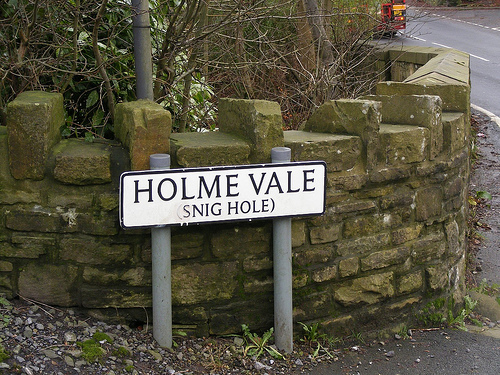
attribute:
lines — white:
[418, 24, 499, 81]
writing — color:
[132, 166, 317, 226]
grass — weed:
[449, 292, 479, 327]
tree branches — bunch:
[152, 0, 402, 132]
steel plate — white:
[120, 152, 330, 231]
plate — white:
[122, 150, 324, 214]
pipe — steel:
[126, 15, 159, 94]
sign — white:
[116, 160, 331, 228]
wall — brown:
[0, 38, 472, 348]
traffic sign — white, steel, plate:
[117, 158, 329, 230]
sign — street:
[120, 165, 332, 222]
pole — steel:
[268, 214, 309, 355]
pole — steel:
[149, 226, 171, 347]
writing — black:
[133, 167, 315, 219]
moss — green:
[64, 310, 179, 372]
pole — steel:
[145, 151, 180, 349]